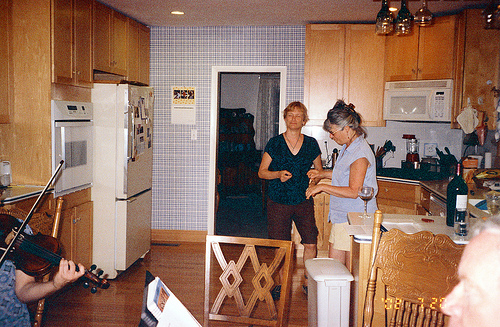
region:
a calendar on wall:
[169, 87, 196, 125]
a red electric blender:
[406, 138, 419, 162]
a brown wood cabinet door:
[303, 21, 343, 127]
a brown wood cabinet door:
[342, 22, 387, 127]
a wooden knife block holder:
[431, 143, 458, 173]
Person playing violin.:
[0, 153, 127, 325]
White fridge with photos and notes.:
[92, 83, 156, 275]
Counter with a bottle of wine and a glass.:
[352, 160, 488, 242]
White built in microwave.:
[378, 70, 460, 130]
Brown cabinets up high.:
[0, 0, 156, 90]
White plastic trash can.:
[307, 254, 354, 325]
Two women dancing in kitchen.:
[264, 98, 376, 270]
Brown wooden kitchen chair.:
[199, 232, 293, 324]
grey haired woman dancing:
[305, 100, 377, 257]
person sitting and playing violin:
[0, 160, 109, 325]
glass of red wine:
[360, 183, 374, 214]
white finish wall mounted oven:
[50, 98, 93, 193]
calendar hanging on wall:
[171, 85, 196, 125]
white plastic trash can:
[304, 259, 353, 325]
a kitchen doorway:
[208, 68, 287, 236]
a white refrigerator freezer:
[94, 82, 154, 279]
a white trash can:
[303, 253, 351, 325]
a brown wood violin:
[1, 209, 112, 294]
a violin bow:
[1, 157, 66, 265]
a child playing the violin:
[1, 157, 109, 326]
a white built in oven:
[51, 99, 93, 195]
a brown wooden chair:
[203, 233, 290, 325]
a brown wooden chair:
[357, 206, 463, 326]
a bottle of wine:
[445, 158, 466, 225]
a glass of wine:
[356, 184, 373, 216]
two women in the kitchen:
[254, 92, 376, 304]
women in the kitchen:
[251, 98, 381, 306]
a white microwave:
[379, 76, 455, 125]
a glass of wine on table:
[356, 181, 378, 220]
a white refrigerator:
[87, 75, 159, 283]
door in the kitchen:
[202, 59, 292, 245]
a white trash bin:
[300, 254, 355, 324]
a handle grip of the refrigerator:
[126, 102, 137, 164]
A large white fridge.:
[92, 77, 155, 278]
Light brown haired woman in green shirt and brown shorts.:
[257, 101, 322, 293]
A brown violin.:
[0, 210, 110, 292]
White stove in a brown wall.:
[50, 98, 92, 196]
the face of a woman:
[321, 129, 346, 151]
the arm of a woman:
[320, 161, 371, 213]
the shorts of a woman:
[322, 209, 366, 260]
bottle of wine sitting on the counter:
[448, 157, 469, 228]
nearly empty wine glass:
[359, 184, 374, 218]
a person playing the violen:
[0, 206, 110, 293]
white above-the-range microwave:
[384, 79, 448, 120]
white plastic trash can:
[311, 261, 351, 323]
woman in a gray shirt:
[324, 99, 379, 183]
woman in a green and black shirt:
[269, 105, 315, 180]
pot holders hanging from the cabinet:
[457, 104, 480, 132]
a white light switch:
[189, 127, 198, 141]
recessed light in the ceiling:
[171, 7, 188, 19]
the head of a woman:
[281, 98, 311, 140]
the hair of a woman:
[282, 101, 304, 116]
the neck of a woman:
[285, 121, 303, 141]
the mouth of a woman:
[290, 121, 298, 129]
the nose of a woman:
[281, 115, 305, 125]